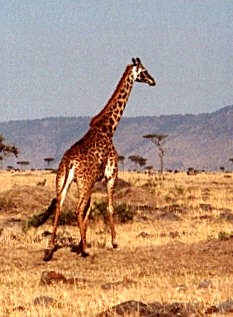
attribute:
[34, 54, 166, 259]
giraffe — tall, detail pattern, white, brown, spotted, standing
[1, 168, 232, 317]
pasture — brown, dry, yellow, rough looking, grassy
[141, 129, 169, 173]
tree — tall, skinny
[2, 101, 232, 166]
hills — far away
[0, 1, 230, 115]
sky — blue, clear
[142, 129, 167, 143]
leaves — green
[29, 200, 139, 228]
plants — green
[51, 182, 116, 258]
legs — verylong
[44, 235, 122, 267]
feet — darker fur